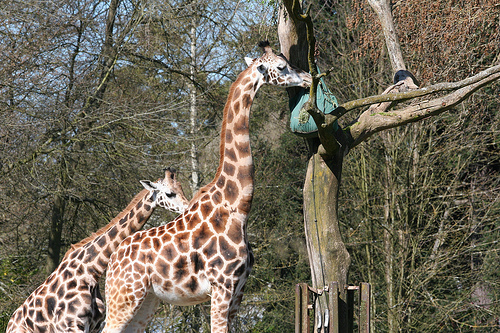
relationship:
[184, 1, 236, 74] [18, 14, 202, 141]
blue skies behind tree branches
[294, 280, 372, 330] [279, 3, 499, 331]
fence around tree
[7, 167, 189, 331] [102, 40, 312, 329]
giraffe with giraffe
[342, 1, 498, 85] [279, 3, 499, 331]
leaves on tree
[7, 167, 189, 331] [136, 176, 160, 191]
giraffe has ear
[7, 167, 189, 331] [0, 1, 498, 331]
giraffe standing by trees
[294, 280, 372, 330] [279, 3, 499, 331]
posts around tree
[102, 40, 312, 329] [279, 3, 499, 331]
giraffe by tree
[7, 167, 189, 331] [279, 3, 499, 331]
giraffe by tree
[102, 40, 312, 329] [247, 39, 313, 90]
giraffe has head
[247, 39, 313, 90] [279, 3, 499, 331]
head by tree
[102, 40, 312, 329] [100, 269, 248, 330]
giraffe has legs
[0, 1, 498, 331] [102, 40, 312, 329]
trees behind giraffe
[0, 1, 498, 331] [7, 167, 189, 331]
trees behind giraffe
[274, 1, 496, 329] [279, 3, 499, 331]
moss on tree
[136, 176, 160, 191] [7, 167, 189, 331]
ear on giraffe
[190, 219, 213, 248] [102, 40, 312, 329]
spot on giraffe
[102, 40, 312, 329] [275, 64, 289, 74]
giraffe has eye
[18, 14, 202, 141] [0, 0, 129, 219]
tree branches on tree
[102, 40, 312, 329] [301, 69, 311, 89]
giraffe has mouth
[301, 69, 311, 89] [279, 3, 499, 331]
mouth on tree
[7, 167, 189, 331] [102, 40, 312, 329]
giraffe standing next to giraffe